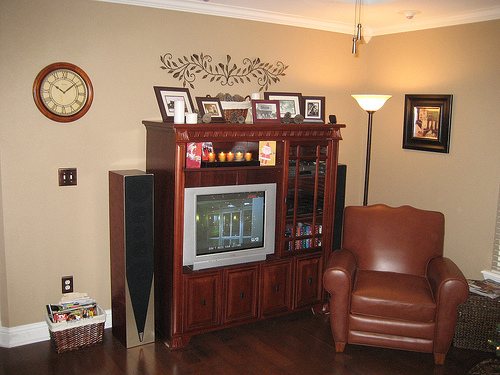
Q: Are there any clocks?
A: Yes, there is a clock.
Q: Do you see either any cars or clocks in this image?
A: Yes, there is a clock.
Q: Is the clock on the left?
A: Yes, the clock is on the left of the image.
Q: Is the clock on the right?
A: No, the clock is on the left of the image.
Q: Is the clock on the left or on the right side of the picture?
A: The clock is on the left of the image.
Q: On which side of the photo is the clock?
A: The clock is on the left of the image.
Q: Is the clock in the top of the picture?
A: Yes, the clock is in the top of the image.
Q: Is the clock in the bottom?
A: No, the clock is in the top of the image.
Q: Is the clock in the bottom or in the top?
A: The clock is in the top of the image.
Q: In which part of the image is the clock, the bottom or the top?
A: The clock is in the top of the image.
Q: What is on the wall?
A: The clock is on the wall.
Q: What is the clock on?
A: The clock is on the wall.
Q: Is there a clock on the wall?
A: Yes, there is a clock on the wall.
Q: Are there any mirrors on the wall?
A: No, there is a clock on the wall.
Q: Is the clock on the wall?
A: Yes, the clock is on the wall.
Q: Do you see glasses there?
A: No, there are no glasses.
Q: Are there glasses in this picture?
A: No, there are no glasses.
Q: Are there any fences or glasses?
A: No, there are no glasses or fences.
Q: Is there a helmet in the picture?
A: No, there are no helmets.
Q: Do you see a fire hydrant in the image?
A: No, there are no fire hydrants.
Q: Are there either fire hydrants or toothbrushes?
A: No, there are no fire hydrants or toothbrushes.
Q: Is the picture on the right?
A: Yes, the picture is on the right of the image.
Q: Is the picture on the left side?
A: No, the picture is on the right of the image.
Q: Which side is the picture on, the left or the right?
A: The picture is on the right of the image.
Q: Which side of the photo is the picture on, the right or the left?
A: The picture is on the right of the image.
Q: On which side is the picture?
A: The picture is on the right of the image.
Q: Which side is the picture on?
A: The picture is on the right of the image.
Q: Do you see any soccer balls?
A: No, there are no soccer balls.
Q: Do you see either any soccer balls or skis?
A: No, there are no soccer balls or skis.